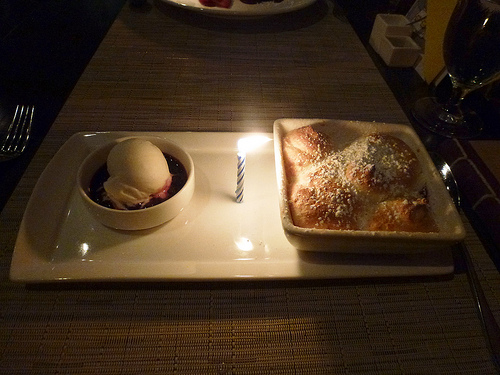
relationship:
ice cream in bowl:
[102, 138, 172, 204] [75, 136, 192, 233]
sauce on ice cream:
[91, 155, 182, 210] [102, 138, 172, 204]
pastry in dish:
[283, 123, 436, 229] [271, 116, 466, 256]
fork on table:
[4, 98, 37, 164] [4, 0, 500, 371]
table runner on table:
[4, 3, 495, 369] [4, 0, 500, 371]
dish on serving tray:
[271, 116, 466, 256] [9, 123, 456, 280]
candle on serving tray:
[231, 127, 272, 206] [9, 123, 456, 280]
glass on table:
[414, 3, 495, 141] [4, 0, 500, 371]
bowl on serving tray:
[75, 136, 192, 233] [9, 123, 456, 280]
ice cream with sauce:
[102, 138, 172, 204] [91, 155, 182, 210]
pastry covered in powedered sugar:
[283, 123, 436, 229] [311, 138, 405, 218]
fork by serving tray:
[4, 98, 37, 164] [9, 123, 456, 280]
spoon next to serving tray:
[428, 146, 495, 357] [9, 123, 456, 280]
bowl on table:
[75, 136, 192, 233] [4, 0, 500, 371]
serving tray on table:
[9, 123, 456, 280] [4, 0, 500, 371]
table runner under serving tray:
[4, 3, 495, 369] [9, 123, 456, 280]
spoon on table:
[428, 146, 495, 357] [4, 0, 500, 371]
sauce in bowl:
[91, 155, 182, 210] [75, 136, 192, 233]